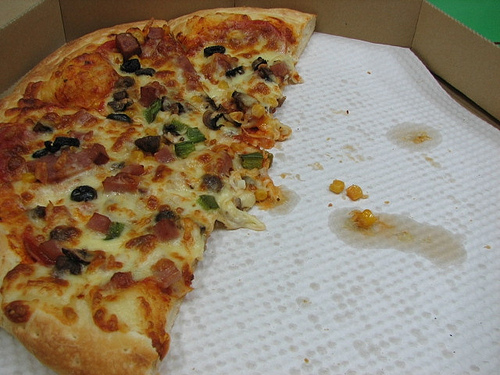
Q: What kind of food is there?
A: Pizza.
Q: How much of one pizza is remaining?
A: Half.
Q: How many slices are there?
A: Four.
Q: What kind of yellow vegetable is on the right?
A: Corn.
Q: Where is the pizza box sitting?
A: On a table.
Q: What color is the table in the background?
A: Green.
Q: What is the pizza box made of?
A: Cardboard.